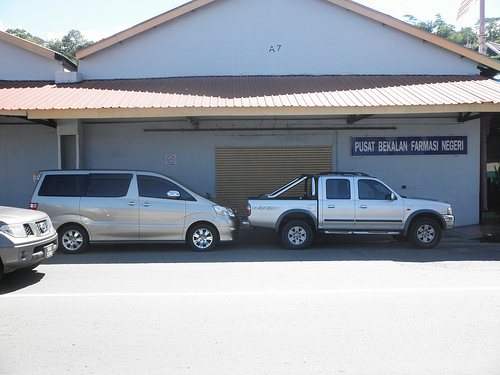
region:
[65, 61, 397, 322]
silver car city here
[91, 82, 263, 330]
silver car city here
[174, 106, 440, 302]
silver car city here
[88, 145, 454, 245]
silver car city here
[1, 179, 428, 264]
silver car city here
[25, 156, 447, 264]
two cars parked on road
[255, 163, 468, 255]
white pick up truck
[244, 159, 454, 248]
white pick up truck parked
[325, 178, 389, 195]
windows on side of truck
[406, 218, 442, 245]
front black wheel of truck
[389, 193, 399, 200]
side view mirror of truck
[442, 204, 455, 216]
front white lights of trucks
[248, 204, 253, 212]
back red lights of truck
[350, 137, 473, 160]
blue sign on wall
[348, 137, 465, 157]
white writing on sign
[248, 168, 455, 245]
Car parked next to a building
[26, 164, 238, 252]
Car parked next to a building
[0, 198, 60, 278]
Car parked next to a building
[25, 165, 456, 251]
Car parked next to a building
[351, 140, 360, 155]
letter p on sign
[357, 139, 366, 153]
letter u on sign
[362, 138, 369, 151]
letter s on sign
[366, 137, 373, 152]
letter a on sign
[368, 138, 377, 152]
letter t on sign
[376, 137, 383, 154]
letter b on sign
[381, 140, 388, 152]
letter e on sign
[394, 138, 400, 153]
letter l on sign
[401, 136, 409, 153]
letter n on sign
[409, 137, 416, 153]
letter f on sign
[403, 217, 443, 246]
tire on the automobile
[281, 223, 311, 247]
tire on the automobile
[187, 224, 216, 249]
tire on the automobile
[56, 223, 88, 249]
tire on the automobile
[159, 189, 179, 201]
side mirror on the automobile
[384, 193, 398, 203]
side mirror on the automobile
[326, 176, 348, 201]
window on the automobile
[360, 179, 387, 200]
window on the automobile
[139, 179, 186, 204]
window on the automobile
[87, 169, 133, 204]
window on the automobile